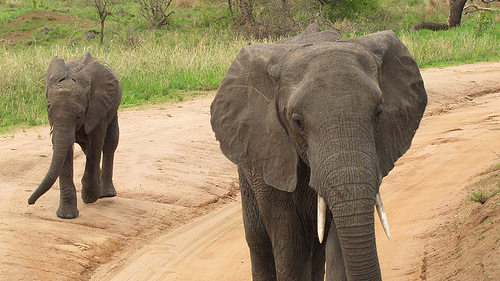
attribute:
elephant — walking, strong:
[209, 27, 427, 278]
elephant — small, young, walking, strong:
[29, 53, 121, 218]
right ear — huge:
[212, 43, 300, 191]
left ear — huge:
[355, 31, 427, 182]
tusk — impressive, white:
[316, 194, 327, 242]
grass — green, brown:
[0, 3, 498, 139]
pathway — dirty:
[1, 59, 499, 275]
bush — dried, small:
[229, 1, 320, 37]